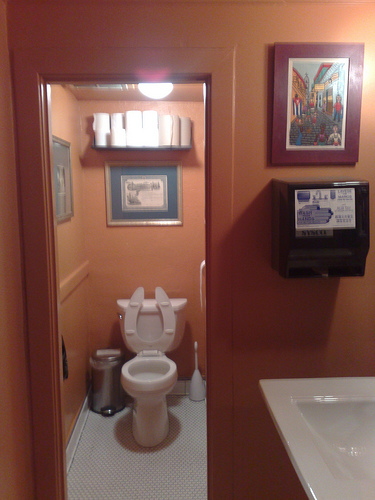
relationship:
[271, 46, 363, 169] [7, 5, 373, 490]
picture on wall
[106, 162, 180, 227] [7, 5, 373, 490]
picture on wall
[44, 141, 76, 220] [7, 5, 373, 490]
picture on wall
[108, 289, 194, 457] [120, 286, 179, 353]
toilet bowl has seat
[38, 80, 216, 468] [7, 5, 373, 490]
bathroom has wall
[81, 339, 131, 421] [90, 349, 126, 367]
trash can has lid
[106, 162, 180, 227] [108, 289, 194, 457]
picture above toilet bowl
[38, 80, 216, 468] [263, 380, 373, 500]
bathroom has sink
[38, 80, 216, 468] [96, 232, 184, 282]
bathroom on orange wall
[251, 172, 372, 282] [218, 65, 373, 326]
dispenser on wall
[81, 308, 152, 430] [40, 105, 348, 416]
trash can in bathroom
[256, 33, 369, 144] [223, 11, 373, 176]
art on wall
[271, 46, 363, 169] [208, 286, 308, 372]
picture hanging on wall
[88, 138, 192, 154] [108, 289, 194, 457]
shelf above toilet bowl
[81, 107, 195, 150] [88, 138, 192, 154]
toilet paper on shelf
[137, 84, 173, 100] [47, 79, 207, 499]
light in restroom